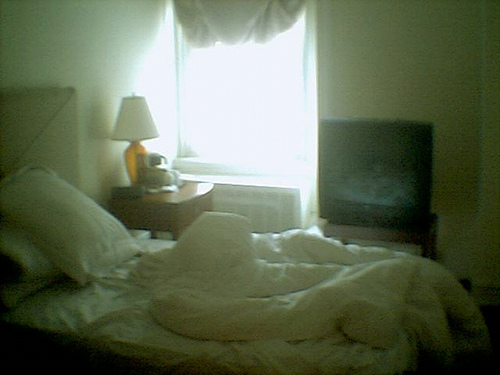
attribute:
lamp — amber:
[110, 94, 158, 189]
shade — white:
[110, 91, 161, 144]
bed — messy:
[1, 223, 424, 374]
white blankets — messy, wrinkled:
[133, 210, 492, 360]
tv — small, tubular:
[313, 116, 434, 228]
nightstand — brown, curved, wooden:
[105, 177, 220, 240]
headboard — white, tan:
[0, 87, 95, 227]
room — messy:
[0, 0, 490, 371]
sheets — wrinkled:
[25, 289, 163, 358]